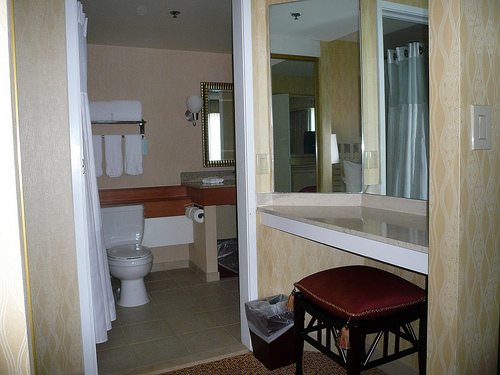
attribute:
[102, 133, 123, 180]
towel — white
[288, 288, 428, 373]
stool — small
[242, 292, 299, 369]
wastebasket — small, black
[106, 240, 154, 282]
toilet bowl — white, ceramic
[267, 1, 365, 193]
mirror — large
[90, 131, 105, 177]
towel — white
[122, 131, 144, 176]
towel — white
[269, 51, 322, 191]
mirror — giant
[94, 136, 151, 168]
towels — white, hanging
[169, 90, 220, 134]
fixture — unlit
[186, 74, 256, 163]
mirror — gold framed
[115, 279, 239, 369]
tile — square, beige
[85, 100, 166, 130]
towels — white, folded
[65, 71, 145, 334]
curtain — white, hanging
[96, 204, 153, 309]
toilet — white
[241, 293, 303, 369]
trash bin — black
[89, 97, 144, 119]
towels — white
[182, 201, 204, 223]
toilet paper — white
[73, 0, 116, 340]
shower curtain — white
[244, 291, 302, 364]
trash bin — dark colored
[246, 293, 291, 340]
trash bag — clear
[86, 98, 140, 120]
towels — Folded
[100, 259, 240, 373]
flooring — beige, tile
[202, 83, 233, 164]
mirror — gold framed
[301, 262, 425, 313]
pillow — red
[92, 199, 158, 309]
toilet — white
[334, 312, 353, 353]
tassel — gold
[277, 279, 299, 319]
tassel — gold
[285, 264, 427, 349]
pillow — red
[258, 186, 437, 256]
counter top — shiny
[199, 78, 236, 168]
frame — gold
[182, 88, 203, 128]
light — white